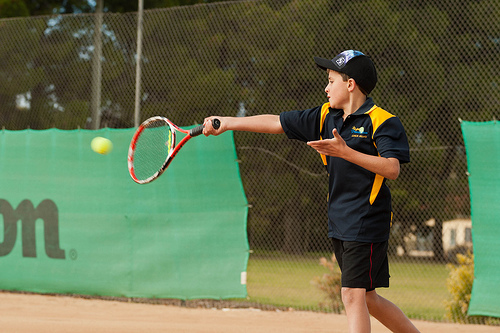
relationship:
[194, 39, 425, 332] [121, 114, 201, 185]
boy holding racquet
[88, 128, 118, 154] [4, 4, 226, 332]
ball in air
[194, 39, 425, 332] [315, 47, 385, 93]
boy wearing a cap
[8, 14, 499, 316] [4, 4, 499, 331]
fence behind court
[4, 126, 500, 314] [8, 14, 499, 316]
material attached to fence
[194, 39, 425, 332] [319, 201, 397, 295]
boy wearing shorts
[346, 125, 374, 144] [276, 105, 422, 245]
word on shirt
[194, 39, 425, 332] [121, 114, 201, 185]
boy hitting racquet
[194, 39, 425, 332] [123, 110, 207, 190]
boy holding tennis racket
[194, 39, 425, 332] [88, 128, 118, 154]
boy hitting ball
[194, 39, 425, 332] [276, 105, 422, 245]
boy wearing a shirt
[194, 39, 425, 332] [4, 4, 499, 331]
boy at a tennis court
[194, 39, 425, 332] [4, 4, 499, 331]
boy on a court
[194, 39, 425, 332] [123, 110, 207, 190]
boy swinging a tennis racket